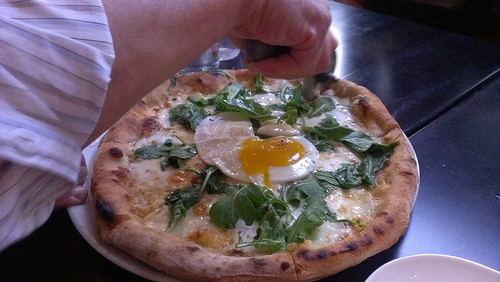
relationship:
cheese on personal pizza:
[316, 135, 401, 240] [90, 66, 420, 281]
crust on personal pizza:
[89, 65, 419, 280] [90, 66, 420, 281]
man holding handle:
[0, 0, 339, 250] [237, 37, 270, 62]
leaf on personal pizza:
[305, 114, 345, 145] [90, 66, 420, 281]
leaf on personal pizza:
[314, 115, 351, 149] [90, 66, 420, 281]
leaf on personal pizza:
[171, 99, 201, 132] [90, 66, 420, 281]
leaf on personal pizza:
[160, 189, 203, 223] [90, 66, 420, 281]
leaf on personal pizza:
[283, 173, 320, 199] [90, 66, 420, 281]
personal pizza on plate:
[90, 66, 420, 281] [68, 128, 166, 280]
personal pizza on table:
[90, 66, 420, 281] [1, 0, 497, 280]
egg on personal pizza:
[191, 108, 320, 189] [87, 66, 422, 279]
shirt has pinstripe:
[0, 0, 123, 197] [0, 4, 81, 238]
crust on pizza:
[89, 65, 419, 281] [76, 40, 443, 277]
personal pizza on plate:
[90, 66, 420, 281] [66, 59, 420, 279]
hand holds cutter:
[225, 0, 340, 84] [242, 30, 337, 102]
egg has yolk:
[191, 108, 320, 189] [231, 122, 306, 174]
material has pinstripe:
[4, 0, 118, 240] [6, 4, 121, 238]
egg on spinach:
[196, 108, 321, 187] [208, 180, 328, 235]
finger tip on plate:
[70, 183, 90, 203] [68, 128, 420, 281]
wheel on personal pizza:
[299, 72, 334, 97] [90, 66, 420, 281]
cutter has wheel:
[215, 30, 350, 95] [299, 72, 334, 97]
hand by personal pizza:
[225, 0, 338, 80] [90, 66, 420, 281]